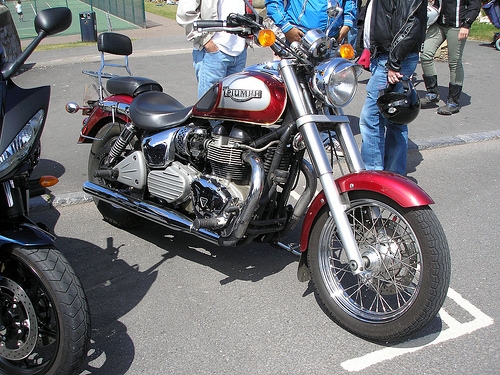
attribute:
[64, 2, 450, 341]
motorcycle — red, parked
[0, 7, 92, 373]
motorcycle — black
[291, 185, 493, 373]
lines — white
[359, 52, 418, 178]
jeans — light, blue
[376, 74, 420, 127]
helmet — black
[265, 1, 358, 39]
jacket — blue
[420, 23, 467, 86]
pants — green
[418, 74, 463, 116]
boots — black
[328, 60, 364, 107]
headlight — large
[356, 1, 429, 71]
jacket — black, leather